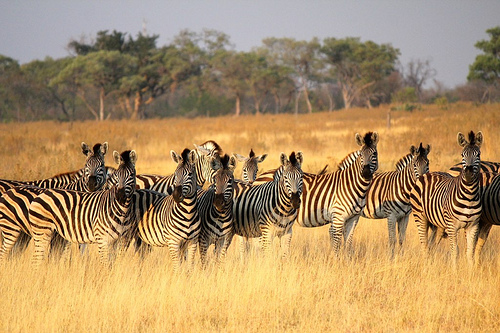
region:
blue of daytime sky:
[3, 1, 498, 81]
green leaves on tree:
[468, 26, 497, 82]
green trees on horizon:
[3, 28, 498, 121]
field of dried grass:
[1, 107, 497, 329]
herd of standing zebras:
[0, 131, 497, 266]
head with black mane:
[353, 131, 378, 182]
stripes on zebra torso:
[53, 193, 98, 240]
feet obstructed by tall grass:
[0, 238, 496, 281]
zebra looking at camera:
[236, 151, 305, 256]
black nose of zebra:
[360, 165, 375, 182]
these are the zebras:
[6, 121, 493, 241]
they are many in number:
[1, 119, 485, 248]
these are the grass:
[245, 255, 375, 321]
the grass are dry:
[218, 242, 354, 331]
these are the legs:
[321, 220, 351, 252]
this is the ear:
[352, 132, 364, 145]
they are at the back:
[242, 43, 353, 102]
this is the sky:
[354, 8, 381, 28]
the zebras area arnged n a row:
[61, 97, 488, 284]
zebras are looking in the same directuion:
[56, 158, 498, 220]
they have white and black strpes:
[93, 114, 451, 287]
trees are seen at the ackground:
[101, 22, 408, 159]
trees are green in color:
[128, 36, 306, 108]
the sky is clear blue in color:
[348, 8, 421, 31]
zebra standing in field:
[403, 128, 485, 275]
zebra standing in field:
[451, 151, 496, 266]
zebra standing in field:
[358, 141, 427, 251]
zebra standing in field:
[296, 128, 381, 252]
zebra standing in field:
[230, 149, 306, 247]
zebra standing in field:
[230, 147, 265, 184]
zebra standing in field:
[197, 153, 240, 260]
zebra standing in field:
[135, 148, 200, 264]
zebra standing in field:
[27, 145, 140, 259]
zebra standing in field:
[2, 138, 104, 255]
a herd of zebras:
[0, 128, 497, 277]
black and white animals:
[0, 123, 499, 271]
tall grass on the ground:
[1, 120, 499, 330]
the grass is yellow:
[0, 113, 490, 329]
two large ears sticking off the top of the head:
[453, 128, 487, 150]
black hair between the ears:
[289, 148, 299, 170]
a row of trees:
[0, 15, 448, 117]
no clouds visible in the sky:
[0, 0, 498, 88]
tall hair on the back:
[336, 143, 361, 175]